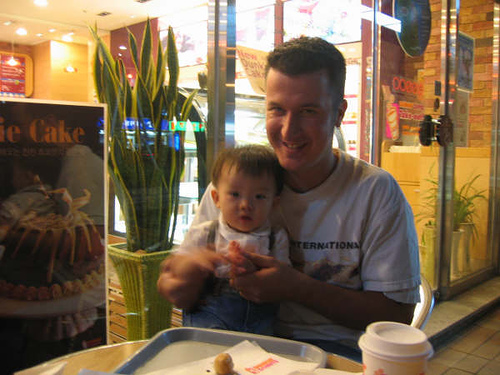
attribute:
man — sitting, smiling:
[159, 34, 421, 374]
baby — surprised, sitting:
[168, 140, 296, 338]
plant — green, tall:
[84, 27, 197, 340]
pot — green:
[108, 243, 181, 340]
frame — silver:
[371, 2, 494, 322]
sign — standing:
[2, 84, 110, 366]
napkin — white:
[203, 344, 318, 373]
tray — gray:
[110, 317, 328, 371]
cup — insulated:
[361, 317, 432, 375]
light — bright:
[0, 2, 138, 85]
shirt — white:
[186, 145, 418, 354]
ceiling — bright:
[1, 1, 384, 71]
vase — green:
[423, 218, 451, 292]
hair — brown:
[209, 143, 287, 208]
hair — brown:
[261, 33, 352, 109]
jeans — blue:
[179, 278, 283, 340]